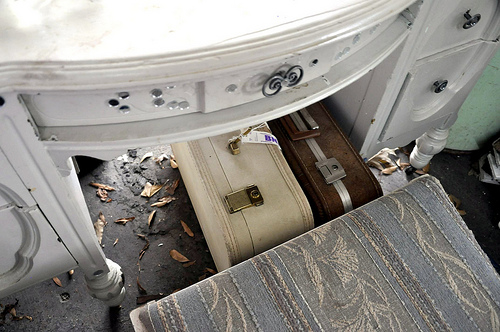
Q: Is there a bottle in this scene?
A: No, there are no bottles.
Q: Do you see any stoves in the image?
A: No, there are no stoves.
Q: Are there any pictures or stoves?
A: No, there are no stoves or pictures.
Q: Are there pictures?
A: No, there are no pictures.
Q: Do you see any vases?
A: No, there are no vases.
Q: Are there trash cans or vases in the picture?
A: No, there are no vases or trash cans.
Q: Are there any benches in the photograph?
A: Yes, there is a bench.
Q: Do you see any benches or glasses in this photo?
A: Yes, there is a bench.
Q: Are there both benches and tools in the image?
A: No, there is a bench but no tools.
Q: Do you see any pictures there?
A: No, there are no pictures.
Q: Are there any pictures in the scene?
A: No, there are no pictures.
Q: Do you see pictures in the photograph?
A: No, there are no pictures.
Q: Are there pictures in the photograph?
A: No, there are no pictures.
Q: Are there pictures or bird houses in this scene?
A: No, there are no pictures or bird houses.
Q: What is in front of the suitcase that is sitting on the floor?
A: The bench is in front of the suitcase.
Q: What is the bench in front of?
A: The bench is in front of the suitcase.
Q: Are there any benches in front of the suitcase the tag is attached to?
A: Yes, there is a bench in front of the suitcase.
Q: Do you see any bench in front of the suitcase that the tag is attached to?
A: Yes, there is a bench in front of the suitcase.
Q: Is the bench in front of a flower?
A: No, the bench is in front of the suitcase.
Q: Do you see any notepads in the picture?
A: No, there are no notepads.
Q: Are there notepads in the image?
A: No, there are no notepads.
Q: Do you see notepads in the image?
A: No, there are no notepads.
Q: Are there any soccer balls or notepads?
A: No, there are no notepads or soccer balls.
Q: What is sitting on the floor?
A: The suitcase is sitting on the floor.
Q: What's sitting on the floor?
A: The suitcase is sitting on the floor.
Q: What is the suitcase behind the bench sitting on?
A: The suitcase is sitting on the floor.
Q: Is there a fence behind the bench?
A: No, there is a suitcase behind the bench.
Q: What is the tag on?
A: The tag is on the suitcase.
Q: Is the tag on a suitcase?
A: Yes, the tag is on a suitcase.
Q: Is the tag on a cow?
A: No, the tag is on a suitcase.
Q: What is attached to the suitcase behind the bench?
A: The tag is attached to the suitcase.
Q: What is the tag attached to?
A: The tag is attached to the suitcase.